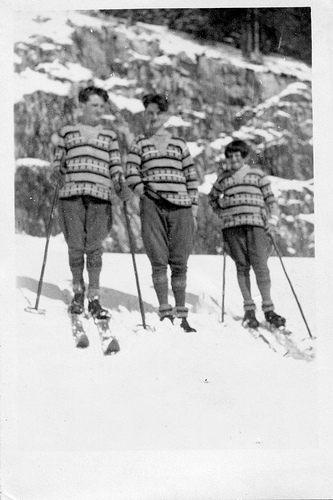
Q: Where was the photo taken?
A: At a ski slope.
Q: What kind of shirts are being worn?
A: Sweaters.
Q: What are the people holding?
A: Ski poles.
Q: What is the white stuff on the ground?
A: Snow.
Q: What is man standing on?
A: Skis.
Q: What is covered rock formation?
A: Snow.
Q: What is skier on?
A: Slope.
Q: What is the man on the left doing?
A: Skiing.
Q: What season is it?
A: Winter.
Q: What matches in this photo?
A: The outfits.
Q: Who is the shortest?
A: The girl on the right.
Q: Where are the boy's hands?
A: His pocket.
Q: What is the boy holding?
A: Ski Poles.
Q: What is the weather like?
A: Snowy.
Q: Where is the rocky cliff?
A: Behind them.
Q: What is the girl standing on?
A: Skis.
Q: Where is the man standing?
A: Snow.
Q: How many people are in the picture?
A: Three.